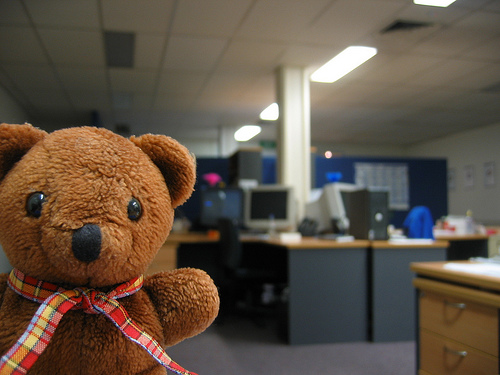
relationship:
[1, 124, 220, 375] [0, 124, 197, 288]
teddy bear has head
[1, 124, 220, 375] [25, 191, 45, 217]
teddy bear has eye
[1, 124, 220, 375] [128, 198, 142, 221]
teddy bear has eye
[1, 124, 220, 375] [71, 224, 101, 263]
teddy bear has nose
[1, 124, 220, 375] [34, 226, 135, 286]
teddy bear has mouth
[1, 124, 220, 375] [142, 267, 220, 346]
teddy bear has arm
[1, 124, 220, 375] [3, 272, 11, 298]
teddy bear has arm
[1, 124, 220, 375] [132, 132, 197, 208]
teddy bear has ear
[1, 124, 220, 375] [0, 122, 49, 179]
teddy bear has ear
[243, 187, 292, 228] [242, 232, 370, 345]
monitor on top of desk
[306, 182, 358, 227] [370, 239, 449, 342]
monitor on top of desk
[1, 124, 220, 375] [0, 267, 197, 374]
teddy bear wearing scarf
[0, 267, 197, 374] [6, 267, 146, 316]
scarf around neck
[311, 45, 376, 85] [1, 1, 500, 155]
light on ceiling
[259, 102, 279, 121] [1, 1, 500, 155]
light on ceiling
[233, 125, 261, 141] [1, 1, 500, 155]
light on ceiling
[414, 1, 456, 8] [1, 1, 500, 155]
light on ceiling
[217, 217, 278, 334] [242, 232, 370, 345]
chair next to desk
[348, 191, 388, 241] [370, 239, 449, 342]
computer tower on top of desk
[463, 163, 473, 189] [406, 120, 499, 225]
paper on wall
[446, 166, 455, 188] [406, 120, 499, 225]
paper on wall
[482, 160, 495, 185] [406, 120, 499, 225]
paper on wall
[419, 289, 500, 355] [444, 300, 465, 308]
drawer has handle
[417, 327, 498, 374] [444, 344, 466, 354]
drawer has handle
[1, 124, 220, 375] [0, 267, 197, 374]
teddy bear has scarf